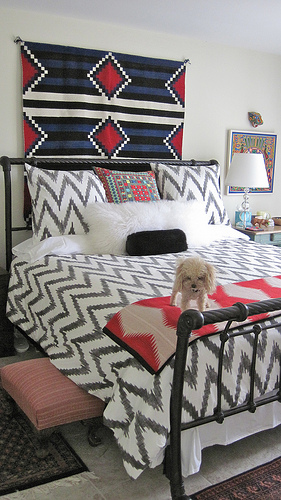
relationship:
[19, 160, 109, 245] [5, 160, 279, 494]
pillow on bed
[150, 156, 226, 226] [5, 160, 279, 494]
pillow on bed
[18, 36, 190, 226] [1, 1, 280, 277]
tapestry on wall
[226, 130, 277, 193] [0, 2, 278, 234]
picture on wall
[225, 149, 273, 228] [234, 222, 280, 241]
lamp on side table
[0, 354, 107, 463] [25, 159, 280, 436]
bench beside bed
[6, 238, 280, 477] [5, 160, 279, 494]
blanket on bed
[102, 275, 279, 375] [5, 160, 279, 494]
blanket on bed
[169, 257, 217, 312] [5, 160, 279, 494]
animal looking at bed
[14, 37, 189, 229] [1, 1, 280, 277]
cloth hanging on wall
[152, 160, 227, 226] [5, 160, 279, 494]
pillow on bed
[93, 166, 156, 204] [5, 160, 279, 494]
pillow on bed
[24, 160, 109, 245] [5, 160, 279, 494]
pillow on bed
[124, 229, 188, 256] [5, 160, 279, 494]
pillow on bed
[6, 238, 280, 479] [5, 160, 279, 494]
comforter on bed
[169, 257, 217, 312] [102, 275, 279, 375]
animal standing on blanket